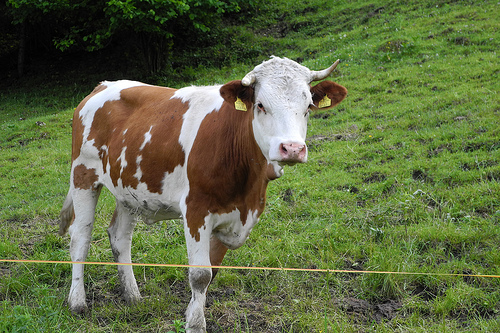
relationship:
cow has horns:
[53, 52, 374, 332] [311, 57, 340, 80]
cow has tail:
[53, 52, 374, 332] [47, 188, 76, 238]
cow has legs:
[53, 52, 374, 332] [65, 155, 100, 316]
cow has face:
[53, 52, 374, 332] [251, 82, 315, 164]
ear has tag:
[218, 81, 258, 113] [232, 97, 249, 114]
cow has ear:
[53, 52, 374, 332] [218, 81, 258, 113]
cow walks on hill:
[53, 52, 374, 332] [0, 0, 500, 331]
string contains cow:
[0, 255, 499, 286] [53, 52, 374, 332]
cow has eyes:
[53, 52, 374, 332] [251, 101, 267, 114]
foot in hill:
[67, 303, 91, 319] [0, 0, 500, 331]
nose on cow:
[279, 141, 306, 163] [53, 52, 374, 332]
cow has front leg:
[53, 52, 374, 332] [180, 205, 216, 332]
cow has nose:
[53, 52, 374, 332] [279, 141, 306, 163]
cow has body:
[53, 52, 374, 332] [68, 75, 285, 250]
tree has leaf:
[2, 1, 88, 80] [15, 1, 22, 8]